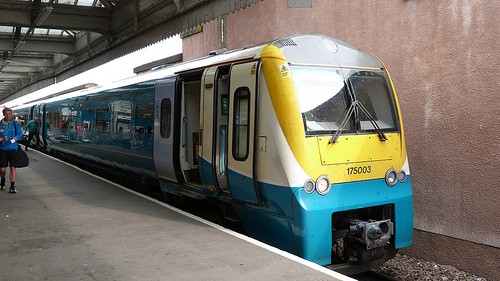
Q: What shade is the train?
A: Blue and yellow.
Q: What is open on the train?
A: The doors.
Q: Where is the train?
A: On the tracks.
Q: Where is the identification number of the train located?
A: On the front.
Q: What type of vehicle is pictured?
A: Train.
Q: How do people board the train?
A: Through the doors.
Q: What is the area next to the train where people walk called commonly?
A: Platform.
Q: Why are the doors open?
A: The train is boarding.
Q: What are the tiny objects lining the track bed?
A: Stones.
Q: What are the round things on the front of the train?
A: Lights.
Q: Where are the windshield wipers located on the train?
A: Below the windshield.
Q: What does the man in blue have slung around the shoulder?
A: Bag.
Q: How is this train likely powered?
A: Electricity.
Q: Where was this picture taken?
A: Train station.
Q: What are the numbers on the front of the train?
A: 175003.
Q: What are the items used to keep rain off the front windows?
A: Windshield wipers.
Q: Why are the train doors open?
A: To let people on an off.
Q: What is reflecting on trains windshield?
A: Light.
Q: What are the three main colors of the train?
A: Yellow, white and blue.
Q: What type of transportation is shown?
A: Train.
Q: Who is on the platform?
A: A girl.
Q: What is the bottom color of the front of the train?
A: Blue.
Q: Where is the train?
A: Stopped at platform.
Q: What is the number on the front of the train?
A: 175003.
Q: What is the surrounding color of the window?
A: Yellow.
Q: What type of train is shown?
A: Subway train.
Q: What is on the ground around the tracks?
A: Gravel.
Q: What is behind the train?
A: A wall.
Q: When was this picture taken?
A: Daytime.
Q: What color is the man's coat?
A: Blue.